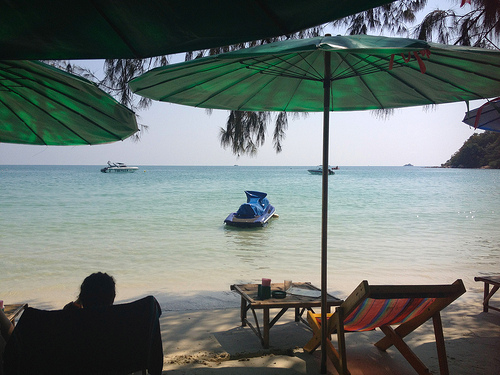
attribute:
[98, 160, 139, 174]
boat — white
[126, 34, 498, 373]
umbrella — green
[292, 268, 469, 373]
chair — wooden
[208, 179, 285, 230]
jet ski — blue, white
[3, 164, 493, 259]
ocean — green 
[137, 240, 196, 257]
ocean wave — white, blue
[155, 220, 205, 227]
ocean wave — white, blue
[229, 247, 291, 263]
ocean wave — white, blue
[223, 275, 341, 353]
table — wooden, low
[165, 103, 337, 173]
sky — pale, blue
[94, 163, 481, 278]
ocean — turqoise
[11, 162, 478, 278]
water — ocean, clear, green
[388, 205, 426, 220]
ocean wave — white and blue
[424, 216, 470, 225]
ocean wave — white and blue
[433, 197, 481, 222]
ocean wave — white and blue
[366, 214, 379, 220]
ocean wave — white and blue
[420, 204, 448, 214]
ocean wave — white and blue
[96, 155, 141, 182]
boat — white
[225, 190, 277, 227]
jet ski — black, blue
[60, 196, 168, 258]
waves — blue 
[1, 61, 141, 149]
umbrella — green, open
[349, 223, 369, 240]
water — green, clear , ocean 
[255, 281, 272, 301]
cup — black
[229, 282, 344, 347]
table — wooden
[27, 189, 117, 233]
wave — blue, white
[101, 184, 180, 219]
waves — white, blue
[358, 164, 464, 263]
waves — white, blue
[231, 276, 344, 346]
table — brown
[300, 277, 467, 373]
chair — red, blue, yellow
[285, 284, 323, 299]
paper — white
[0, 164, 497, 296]
ocean — white, blue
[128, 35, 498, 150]
umbrella — open, green, opened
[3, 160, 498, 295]
water — green, clear, ocean, large 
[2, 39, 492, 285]
umbrellas — open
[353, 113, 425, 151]
sky — blue, clear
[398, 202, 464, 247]
water — blue, clear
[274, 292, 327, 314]
table — wood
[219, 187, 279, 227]
jet ski — blue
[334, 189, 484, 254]
waves — white, blue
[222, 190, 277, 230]
jet ski — blue, white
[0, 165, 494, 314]
ocean — green